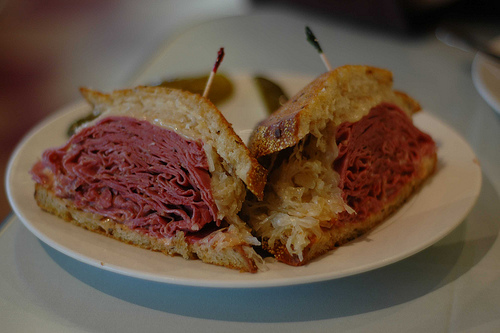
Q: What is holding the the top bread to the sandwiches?
A: Wooden picks.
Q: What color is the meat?
A: Red.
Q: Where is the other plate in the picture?
A: Top right corner.